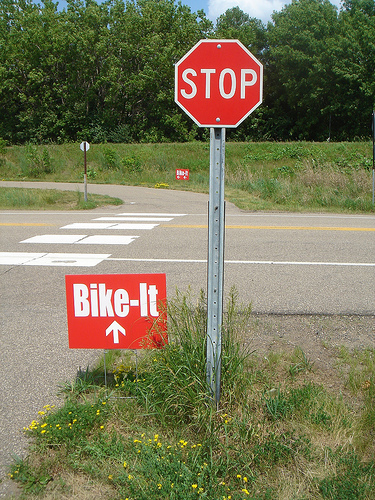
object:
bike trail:
[0, 179, 243, 217]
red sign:
[64, 272, 168, 349]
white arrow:
[105, 320, 126, 343]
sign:
[77, 130, 100, 158]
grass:
[8, 284, 374, 500]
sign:
[175, 169, 189, 180]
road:
[0, 177, 375, 499]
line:
[0, 221, 375, 232]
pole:
[207, 126, 225, 401]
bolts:
[215, 44, 221, 123]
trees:
[0, 0, 375, 147]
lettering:
[180, 68, 257, 100]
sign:
[174, 38, 263, 128]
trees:
[6, 284, 375, 500]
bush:
[133, 284, 258, 468]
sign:
[80, 141, 90, 151]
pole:
[84, 143, 88, 203]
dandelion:
[5, 345, 257, 500]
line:
[115, 211, 187, 217]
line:
[60, 221, 159, 231]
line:
[21, 232, 140, 246]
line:
[0, 250, 112, 268]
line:
[92, 215, 175, 223]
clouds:
[201, 0, 285, 26]